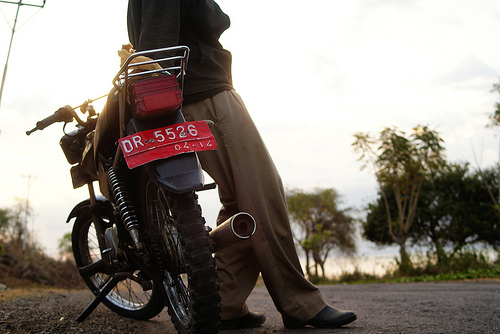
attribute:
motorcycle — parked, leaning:
[24, 44, 257, 331]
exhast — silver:
[209, 211, 258, 255]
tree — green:
[350, 122, 451, 280]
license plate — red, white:
[120, 117, 221, 168]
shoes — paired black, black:
[224, 307, 360, 333]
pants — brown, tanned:
[181, 87, 329, 320]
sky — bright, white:
[2, 0, 498, 281]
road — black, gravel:
[2, 281, 500, 332]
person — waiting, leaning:
[128, 0, 358, 333]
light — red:
[144, 89, 183, 110]